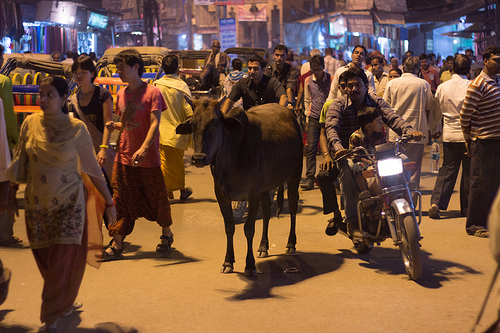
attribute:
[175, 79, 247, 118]
cow — horned, here, standing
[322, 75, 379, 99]
men — riding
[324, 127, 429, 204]
motorcycle — black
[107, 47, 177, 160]
man — walking, standing, worn, young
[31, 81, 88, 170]
woman — walking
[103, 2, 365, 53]
buildings — distant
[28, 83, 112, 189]
girl — walkign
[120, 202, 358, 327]
street — busy, urban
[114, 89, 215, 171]
shirt — red, orange, black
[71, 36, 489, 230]
square — busy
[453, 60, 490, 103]
shirt — striped, purple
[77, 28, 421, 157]
market — busy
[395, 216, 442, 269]
wheel — here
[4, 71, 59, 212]
guard — here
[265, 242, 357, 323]
shade — here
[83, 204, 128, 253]
cloth — here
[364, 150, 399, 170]
light — white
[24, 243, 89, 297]
skirt — red, yellow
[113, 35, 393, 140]
crowd — bustling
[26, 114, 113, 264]
outfit — traditional